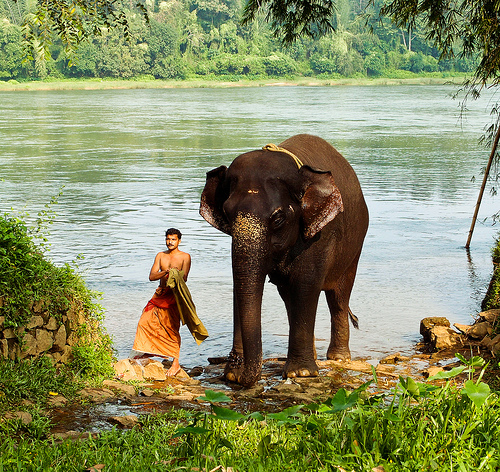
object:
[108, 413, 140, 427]
rocks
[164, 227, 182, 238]
hair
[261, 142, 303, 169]
rope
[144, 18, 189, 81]
bushes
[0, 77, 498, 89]
shore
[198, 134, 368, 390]
elephant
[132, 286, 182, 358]
cloth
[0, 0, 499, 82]
forest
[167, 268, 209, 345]
cloth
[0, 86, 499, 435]
river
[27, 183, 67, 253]
plants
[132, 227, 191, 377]
man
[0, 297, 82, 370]
rock wall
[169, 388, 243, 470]
grass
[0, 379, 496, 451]
water's edge